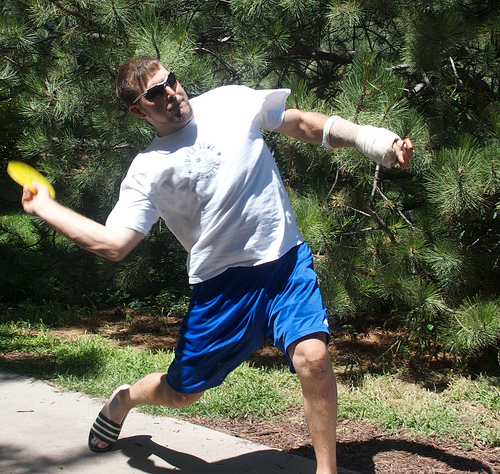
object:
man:
[22, 55, 414, 473]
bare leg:
[286, 333, 338, 472]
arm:
[236, 88, 381, 157]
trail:
[0, 318, 500, 473]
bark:
[372, 169, 380, 204]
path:
[0, 372, 360, 473]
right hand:
[20, 185, 45, 213]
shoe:
[87, 411, 122, 454]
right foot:
[90, 384, 132, 450]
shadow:
[114, 429, 489, 471]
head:
[118, 56, 192, 125]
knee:
[168, 387, 205, 412]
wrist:
[37, 198, 58, 214]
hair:
[116, 56, 159, 109]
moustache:
[143, 101, 193, 126]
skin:
[94, 233, 119, 265]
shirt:
[106, 83, 306, 286]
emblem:
[197, 159, 217, 183]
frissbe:
[6, 158, 56, 198]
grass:
[0, 320, 500, 449]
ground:
[0, 304, 500, 472]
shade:
[360, 335, 455, 368]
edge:
[0, 341, 94, 399]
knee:
[296, 341, 331, 385]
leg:
[129, 370, 205, 407]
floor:
[0, 309, 500, 474]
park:
[0, 2, 500, 474]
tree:
[0, 0, 500, 361]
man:
[21, 84, 414, 473]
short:
[166, 239, 330, 394]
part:
[274, 320, 297, 330]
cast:
[7, 159, 56, 217]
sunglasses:
[133, 71, 178, 104]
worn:
[133, 70, 180, 103]